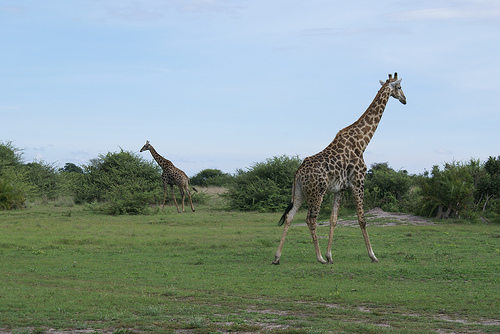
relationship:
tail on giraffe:
[279, 184, 296, 228] [267, 73, 411, 267]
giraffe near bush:
[141, 139, 197, 214] [86, 151, 155, 220]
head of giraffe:
[377, 68, 408, 108] [267, 73, 411, 267]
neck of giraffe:
[342, 95, 392, 148] [267, 73, 411, 267]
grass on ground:
[68, 212, 255, 276] [13, 212, 494, 328]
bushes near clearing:
[232, 158, 498, 214] [195, 155, 237, 211]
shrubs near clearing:
[7, 157, 104, 195] [195, 155, 237, 211]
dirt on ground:
[368, 206, 416, 226] [13, 212, 494, 328]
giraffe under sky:
[141, 139, 197, 214] [11, 0, 498, 155]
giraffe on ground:
[272, 71, 405, 263] [13, 212, 494, 328]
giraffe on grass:
[272, 71, 405, 263] [68, 212, 255, 276]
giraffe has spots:
[267, 73, 411, 267] [328, 141, 356, 186]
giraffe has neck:
[267, 73, 411, 267] [342, 95, 392, 148]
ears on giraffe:
[381, 70, 406, 84] [267, 73, 411, 267]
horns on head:
[385, 66, 399, 83] [377, 68, 408, 108]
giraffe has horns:
[267, 73, 411, 267] [385, 66, 399, 83]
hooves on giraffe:
[269, 252, 386, 271] [267, 73, 411, 267]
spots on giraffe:
[328, 141, 356, 186] [267, 73, 411, 267]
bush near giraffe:
[86, 151, 155, 220] [141, 139, 197, 214]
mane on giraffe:
[349, 101, 375, 126] [267, 73, 411, 267]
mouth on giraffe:
[400, 91, 419, 108] [267, 73, 411, 267]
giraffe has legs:
[267, 73, 411, 267] [265, 186, 375, 272]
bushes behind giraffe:
[232, 158, 498, 214] [267, 73, 411, 267]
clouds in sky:
[193, 5, 491, 65] [11, 0, 498, 155]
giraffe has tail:
[267, 73, 411, 267] [279, 184, 296, 228]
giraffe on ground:
[267, 73, 411, 267] [13, 212, 494, 328]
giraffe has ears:
[267, 73, 411, 267] [381, 70, 406, 84]